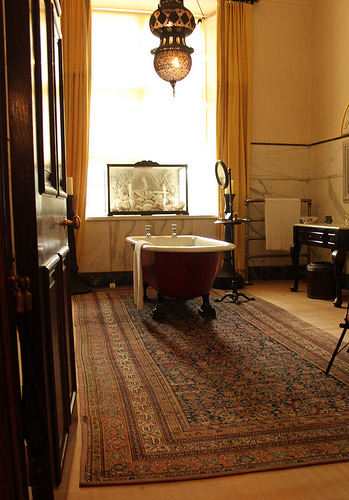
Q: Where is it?
A: This is at the bathroom.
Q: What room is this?
A: It is a bathroom.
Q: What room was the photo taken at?
A: It was taken at the bathroom.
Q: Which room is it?
A: It is a bathroom.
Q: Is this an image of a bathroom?
A: Yes, it is showing a bathroom.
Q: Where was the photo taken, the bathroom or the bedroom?
A: It was taken at the bathroom.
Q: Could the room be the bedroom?
A: No, it is the bathroom.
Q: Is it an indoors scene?
A: Yes, it is indoors.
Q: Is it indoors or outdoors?
A: It is indoors.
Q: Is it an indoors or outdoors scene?
A: It is indoors.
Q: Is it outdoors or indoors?
A: It is indoors.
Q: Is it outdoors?
A: No, it is indoors.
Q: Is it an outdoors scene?
A: No, it is indoors.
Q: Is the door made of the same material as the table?
A: Yes, both the door and the table are made of wood.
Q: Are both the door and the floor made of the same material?
A: Yes, both the door and the floor are made of wood.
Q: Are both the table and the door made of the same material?
A: Yes, both the table and the door are made of wood.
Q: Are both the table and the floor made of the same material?
A: Yes, both the table and the floor are made of wood.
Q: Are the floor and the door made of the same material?
A: Yes, both the floor and the door are made of wood.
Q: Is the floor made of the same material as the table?
A: Yes, both the floor and the table are made of wood.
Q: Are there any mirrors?
A: Yes, there is a mirror.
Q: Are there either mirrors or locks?
A: Yes, there is a mirror.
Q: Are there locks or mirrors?
A: Yes, there is a mirror.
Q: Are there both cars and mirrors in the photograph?
A: No, there is a mirror but no cars.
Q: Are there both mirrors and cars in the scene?
A: No, there is a mirror but no cars.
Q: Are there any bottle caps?
A: No, there are no bottle caps.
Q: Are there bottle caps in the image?
A: No, there are no bottle caps.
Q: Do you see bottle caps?
A: No, there are no bottle caps.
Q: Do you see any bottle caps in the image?
A: No, there are no bottle caps.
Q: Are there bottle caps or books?
A: No, there are no bottle caps or books.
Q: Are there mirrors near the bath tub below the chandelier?
A: Yes, there is a mirror near the tub.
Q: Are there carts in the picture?
A: No, there are no carts.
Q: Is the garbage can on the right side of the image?
A: Yes, the garbage can is on the right of the image.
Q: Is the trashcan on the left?
A: No, the trashcan is on the right of the image.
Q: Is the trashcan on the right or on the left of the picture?
A: The trashcan is on the right of the image.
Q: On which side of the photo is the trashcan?
A: The trashcan is on the right of the image.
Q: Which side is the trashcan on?
A: The trashcan is on the right of the image.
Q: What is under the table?
A: The trash can is under the table.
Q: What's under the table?
A: The trash can is under the table.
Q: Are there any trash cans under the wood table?
A: Yes, there is a trash can under the table.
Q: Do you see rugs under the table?
A: No, there is a trash can under the table.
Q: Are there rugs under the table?
A: No, there is a trash can under the table.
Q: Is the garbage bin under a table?
A: Yes, the garbage bin is under a table.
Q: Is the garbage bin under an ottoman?
A: No, the garbage bin is under a table.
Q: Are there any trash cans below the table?
A: Yes, there is a trash can below the table.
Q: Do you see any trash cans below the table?
A: Yes, there is a trash can below the table.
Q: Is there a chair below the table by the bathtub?
A: No, there is a trash can below the table.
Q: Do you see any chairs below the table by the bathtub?
A: No, there is a trash can below the table.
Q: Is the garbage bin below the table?
A: Yes, the garbage bin is below the table.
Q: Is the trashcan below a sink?
A: No, the trashcan is below the table.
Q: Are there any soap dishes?
A: No, there are no soap dishes.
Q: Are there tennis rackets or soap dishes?
A: No, there are no soap dishes or tennis rackets.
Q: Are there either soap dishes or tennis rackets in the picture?
A: No, there are no soap dishes or tennis rackets.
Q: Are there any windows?
A: Yes, there is a window.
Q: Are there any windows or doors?
A: Yes, there is a window.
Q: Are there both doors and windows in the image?
A: Yes, there are both a window and a door.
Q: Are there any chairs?
A: No, there are no chairs.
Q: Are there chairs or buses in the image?
A: No, there are no chairs or buses.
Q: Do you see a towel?
A: Yes, there is a towel.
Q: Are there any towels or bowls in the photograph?
A: Yes, there is a towel.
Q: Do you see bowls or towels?
A: Yes, there is a towel.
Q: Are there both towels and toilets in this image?
A: No, there is a towel but no toilets.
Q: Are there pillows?
A: No, there are no pillows.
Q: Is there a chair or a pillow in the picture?
A: No, there are no pillows or chairs.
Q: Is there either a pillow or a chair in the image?
A: No, there are no pillows or chairs.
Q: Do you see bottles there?
A: No, there are no bottles.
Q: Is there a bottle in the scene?
A: No, there are no bottles.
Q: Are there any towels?
A: Yes, there is a towel.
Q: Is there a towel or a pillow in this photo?
A: Yes, there is a towel.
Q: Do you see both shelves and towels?
A: No, there is a towel but no shelves.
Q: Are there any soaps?
A: No, there are no soaps.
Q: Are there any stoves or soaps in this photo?
A: No, there are no soaps or stoves.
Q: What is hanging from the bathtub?
A: The towel is hanging from the bathtub.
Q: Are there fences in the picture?
A: No, there are no fences.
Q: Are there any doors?
A: Yes, there is a door.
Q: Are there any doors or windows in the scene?
A: Yes, there is a door.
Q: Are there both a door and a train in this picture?
A: No, there is a door but no trains.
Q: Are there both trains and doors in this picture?
A: No, there is a door but no trains.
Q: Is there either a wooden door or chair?
A: Yes, there is a wood door.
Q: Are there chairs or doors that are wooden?
A: Yes, the door is wooden.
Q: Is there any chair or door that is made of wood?
A: Yes, the door is made of wood.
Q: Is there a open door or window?
A: Yes, there is an open door.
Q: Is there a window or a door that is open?
A: Yes, the door is open.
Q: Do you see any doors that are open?
A: Yes, there is an open door.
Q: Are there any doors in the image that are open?
A: Yes, there is a door that is open.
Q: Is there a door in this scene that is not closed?
A: Yes, there is a open door.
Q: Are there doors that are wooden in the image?
A: Yes, there is a wood door.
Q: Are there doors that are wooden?
A: Yes, there is a door that is wooden.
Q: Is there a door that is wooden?
A: Yes, there is a door that is wooden.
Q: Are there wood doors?
A: Yes, there is a door that is made of wood.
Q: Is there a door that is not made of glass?
A: Yes, there is a door that is made of wood.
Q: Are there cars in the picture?
A: No, there are no cars.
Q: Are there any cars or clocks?
A: No, there are no cars or clocks.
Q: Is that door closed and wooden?
A: No, the door is wooden but open.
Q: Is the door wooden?
A: Yes, the door is wooden.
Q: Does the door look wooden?
A: Yes, the door is wooden.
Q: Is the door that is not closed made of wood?
A: Yes, the door is made of wood.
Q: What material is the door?
A: The door is made of wood.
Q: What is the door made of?
A: The door is made of wood.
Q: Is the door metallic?
A: No, the door is wooden.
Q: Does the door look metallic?
A: No, the door is wooden.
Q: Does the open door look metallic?
A: No, the door is wooden.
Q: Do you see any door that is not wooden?
A: No, there is a door but it is wooden.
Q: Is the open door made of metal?
A: No, the door is made of wood.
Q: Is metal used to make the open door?
A: No, the door is made of wood.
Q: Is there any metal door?
A: No, there is a door but it is made of wood.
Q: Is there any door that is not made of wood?
A: No, there is a door but it is made of wood.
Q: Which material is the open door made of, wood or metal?
A: The door is made of wood.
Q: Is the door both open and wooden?
A: Yes, the door is open and wooden.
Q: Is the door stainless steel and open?
A: No, the door is open but wooden.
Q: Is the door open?
A: Yes, the door is open.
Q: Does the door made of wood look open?
A: Yes, the door is open.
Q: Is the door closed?
A: No, the door is open.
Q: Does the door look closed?
A: No, the door is open.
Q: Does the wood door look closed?
A: No, the door is open.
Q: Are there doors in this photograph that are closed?
A: No, there is a door but it is open.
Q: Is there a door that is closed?
A: No, there is a door but it is open.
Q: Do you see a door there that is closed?
A: No, there is a door but it is open.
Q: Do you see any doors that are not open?
A: No, there is a door but it is open.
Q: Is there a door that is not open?
A: No, there is a door but it is open.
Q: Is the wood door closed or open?
A: The door is open.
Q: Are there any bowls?
A: No, there are no bowls.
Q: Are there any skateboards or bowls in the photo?
A: No, there are no bowls or skateboards.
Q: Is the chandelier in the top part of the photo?
A: Yes, the chandelier is in the top of the image.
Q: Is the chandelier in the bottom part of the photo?
A: No, the chandelier is in the top of the image.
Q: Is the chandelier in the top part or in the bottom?
A: The chandelier is in the top of the image.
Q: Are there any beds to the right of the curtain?
A: No, there is a chandelier to the right of the curtain.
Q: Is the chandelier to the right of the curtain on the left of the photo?
A: Yes, the chandelier is to the right of the curtain.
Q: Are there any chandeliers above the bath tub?
A: Yes, there is a chandelier above the bath tub.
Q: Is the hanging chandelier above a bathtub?
A: Yes, the chandelier is above a bathtub.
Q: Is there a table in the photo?
A: Yes, there is a table.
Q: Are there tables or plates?
A: Yes, there is a table.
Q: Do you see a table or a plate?
A: Yes, there is a table.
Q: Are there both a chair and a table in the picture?
A: No, there is a table but no chairs.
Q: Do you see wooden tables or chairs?
A: Yes, there is a wood table.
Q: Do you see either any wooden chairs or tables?
A: Yes, there is a wood table.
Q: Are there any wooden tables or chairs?
A: Yes, there is a wood table.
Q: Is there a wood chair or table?
A: Yes, there is a wood table.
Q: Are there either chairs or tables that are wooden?
A: Yes, the table is wooden.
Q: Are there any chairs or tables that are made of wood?
A: Yes, the table is made of wood.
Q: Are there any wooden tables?
A: Yes, there is a wood table.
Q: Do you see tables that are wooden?
A: Yes, there is a table that is wooden.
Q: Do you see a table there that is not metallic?
A: Yes, there is a wooden table.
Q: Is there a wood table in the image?
A: Yes, there is a table that is made of wood.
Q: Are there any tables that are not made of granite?
A: Yes, there is a table that is made of wood.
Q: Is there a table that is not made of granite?
A: Yes, there is a table that is made of wood.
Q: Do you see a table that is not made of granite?
A: Yes, there is a table that is made of wood.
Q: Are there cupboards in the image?
A: No, there are no cupboards.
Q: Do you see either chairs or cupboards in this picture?
A: No, there are no cupboards or chairs.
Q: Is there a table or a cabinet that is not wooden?
A: No, there is a table but it is wooden.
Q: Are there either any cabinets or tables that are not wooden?
A: No, there is a table but it is wooden.